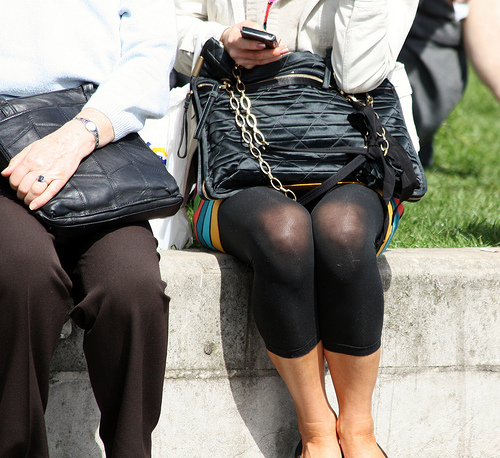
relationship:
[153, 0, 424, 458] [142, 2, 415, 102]
person has shirt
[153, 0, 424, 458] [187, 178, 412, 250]
person has rainbow skirt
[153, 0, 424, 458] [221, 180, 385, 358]
person has leggings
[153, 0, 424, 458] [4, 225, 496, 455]
person sits on concrete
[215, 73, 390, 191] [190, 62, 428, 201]
chain on bag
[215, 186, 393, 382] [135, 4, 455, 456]
leggings on woman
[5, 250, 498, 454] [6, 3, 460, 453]
wall beneath people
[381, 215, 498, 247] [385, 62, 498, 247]
grass behind field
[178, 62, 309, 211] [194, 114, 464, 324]
purse on lap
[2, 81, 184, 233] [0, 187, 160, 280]
purse on lap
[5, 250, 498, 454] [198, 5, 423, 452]
wall under woman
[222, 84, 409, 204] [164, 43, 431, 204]
strap on purse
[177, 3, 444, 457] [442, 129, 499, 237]
person sitting on grass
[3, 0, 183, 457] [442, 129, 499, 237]
person sitting on grass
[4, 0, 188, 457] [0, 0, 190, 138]
woman in shirt